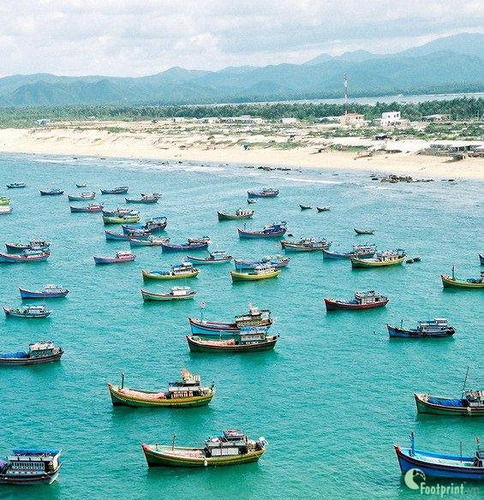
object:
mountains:
[0, 30, 481, 110]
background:
[0, 4, 483, 104]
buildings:
[373, 112, 402, 127]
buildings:
[315, 116, 341, 124]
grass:
[54, 116, 482, 162]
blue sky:
[5, 1, 480, 68]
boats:
[247, 186, 280, 198]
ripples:
[20, 145, 478, 498]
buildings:
[339, 113, 364, 124]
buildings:
[173, 115, 263, 124]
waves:
[32, 152, 409, 195]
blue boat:
[394, 430, 483, 484]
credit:
[416, 479, 466, 496]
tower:
[341, 68, 365, 125]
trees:
[2, 97, 481, 119]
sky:
[0, 0, 481, 71]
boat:
[278, 233, 333, 251]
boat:
[229, 258, 282, 281]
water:
[2, 152, 479, 495]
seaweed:
[25, 116, 481, 145]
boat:
[109, 366, 217, 408]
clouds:
[0, 0, 483, 76]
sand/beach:
[1, 119, 477, 158]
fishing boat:
[183, 325, 279, 352]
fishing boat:
[385, 307, 455, 341]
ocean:
[4, 153, 476, 499]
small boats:
[353, 227, 375, 234]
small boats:
[316, 204, 333, 210]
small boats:
[299, 202, 313, 209]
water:
[138, 91, 483, 108]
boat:
[247, 188, 280, 198]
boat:
[215, 206, 254, 223]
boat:
[125, 192, 163, 203]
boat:
[160, 234, 212, 251]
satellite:
[333, 62, 364, 120]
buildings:
[423, 114, 449, 122]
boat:
[323, 289, 389, 312]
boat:
[385, 317, 457, 338]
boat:
[345, 246, 408, 267]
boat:
[140, 285, 196, 301]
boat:
[237, 219, 287, 236]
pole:
[344, 72, 348, 113]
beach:
[0, 94, 484, 181]